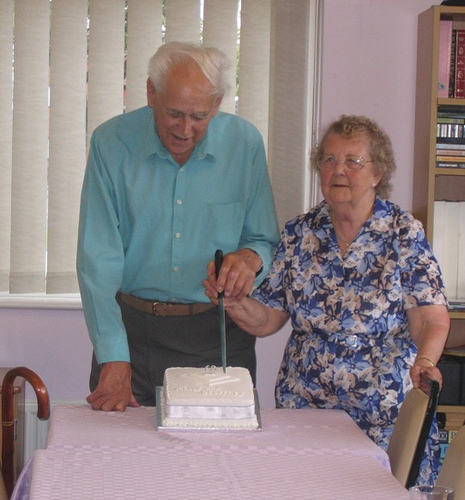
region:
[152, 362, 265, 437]
special cake for celebration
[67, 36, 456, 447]
elderly man and woman living in institutional setting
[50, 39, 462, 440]
Elderly man helping elderly woman cut cake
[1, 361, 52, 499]
wooden walking cane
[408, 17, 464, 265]
bookcase with books and cassette tapes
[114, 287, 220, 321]
man's belt holding up pants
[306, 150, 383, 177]
eyeglasses to help elderly woman see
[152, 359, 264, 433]
cake decorated with white frosting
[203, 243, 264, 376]
knife carefully held by two people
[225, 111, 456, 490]
older woman wearing flowery dress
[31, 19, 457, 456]
Picture is taken outside.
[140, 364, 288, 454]
The cake is white.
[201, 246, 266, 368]
The man and woman are holding a knife.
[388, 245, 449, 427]
The woman's left hand is holding a chair.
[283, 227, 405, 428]
The woman's dress is blue, white and tan in color.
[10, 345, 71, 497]
A wood cane is leaning up next to the table.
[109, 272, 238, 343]
The man's belt is brown in color.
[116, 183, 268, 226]
The man's shirt is teal in color.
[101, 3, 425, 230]
The man and woman are older in age.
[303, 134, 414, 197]
The woman is wearing glasses.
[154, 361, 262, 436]
Cake with vanilla frosting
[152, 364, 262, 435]
White icing on the cake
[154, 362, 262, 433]
Cake from the bakery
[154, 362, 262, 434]
Vanilla cake on the table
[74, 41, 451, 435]
Elderly couple celebrating anniversary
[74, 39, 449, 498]
Anniversary couple cutting a cake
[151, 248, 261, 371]
Knife in couple's hands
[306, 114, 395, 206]
Elderly woman wearing eyeglasses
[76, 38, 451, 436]
Elderly woman and man celebrating a special day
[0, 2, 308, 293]
Vertical blinds covering the window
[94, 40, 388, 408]
old man and woman celebrating with cake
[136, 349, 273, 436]
white congratulations cake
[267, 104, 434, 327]
old woman with blue and white blouse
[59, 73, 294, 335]
old man helping cut cake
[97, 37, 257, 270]
old man with white hair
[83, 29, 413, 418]
old man and woman cutting cake together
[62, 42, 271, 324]
old man in blue shirt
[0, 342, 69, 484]
cane next to a table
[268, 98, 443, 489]
woman hold chair while standing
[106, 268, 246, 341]
brown mens belt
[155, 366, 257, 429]
White anniversary cake.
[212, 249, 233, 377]
Knife to cut the cake held by the happy couple.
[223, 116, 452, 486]
Woman in a blue floral shirt cutting the anniversary cake.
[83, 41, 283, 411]
Older gentleman in a green-blue shirt and brown pants cutting a cake.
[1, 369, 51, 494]
Brown wooden walking cane.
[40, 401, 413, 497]
Table with a pink table cloth.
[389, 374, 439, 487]
Black and beige chair.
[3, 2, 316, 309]
Off-white vertical blinds hanging from window.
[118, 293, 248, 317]
Brown belt holding up pants.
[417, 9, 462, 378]
Bookcase on the far wall.